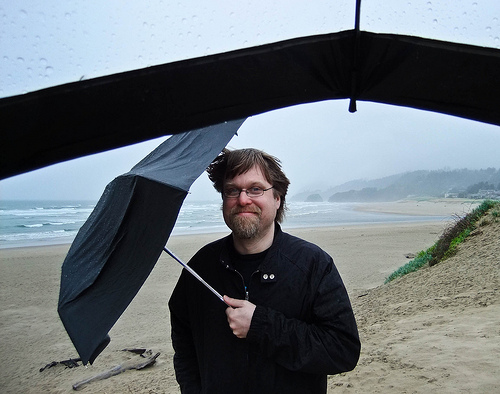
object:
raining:
[1, 1, 122, 87]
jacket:
[167, 223, 361, 394]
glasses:
[220, 182, 275, 198]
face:
[216, 168, 277, 239]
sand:
[0, 202, 499, 393]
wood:
[37, 345, 161, 394]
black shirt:
[168, 222, 362, 394]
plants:
[382, 193, 500, 287]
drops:
[0, 0, 499, 97]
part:
[0, 0, 499, 103]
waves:
[0, 200, 454, 252]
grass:
[380, 199, 500, 286]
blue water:
[0, 197, 453, 247]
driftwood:
[35, 345, 161, 390]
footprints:
[350, 222, 499, 393]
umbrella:
[76, 147, 228, 234]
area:
[0, 0, 499, 393]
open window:
[0, 0, 499, 180]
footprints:
[1, 343, 181, 394]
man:
[167, 147, 361, 393]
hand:
[221, 295, 256, 339]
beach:
[0, 224, 497, 390]